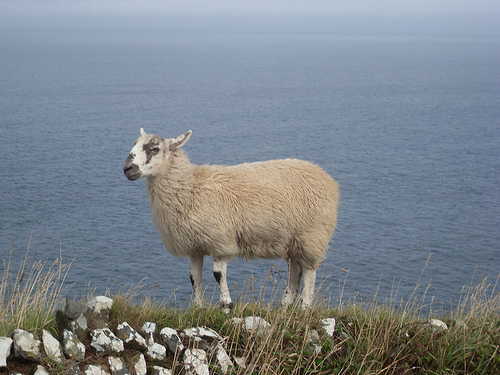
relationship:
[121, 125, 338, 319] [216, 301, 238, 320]
sheep has foot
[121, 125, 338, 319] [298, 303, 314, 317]
sheep has foot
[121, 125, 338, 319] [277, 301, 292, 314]
sheep has foot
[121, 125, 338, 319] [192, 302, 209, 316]
sheep has foot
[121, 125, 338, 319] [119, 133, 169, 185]
sheep has face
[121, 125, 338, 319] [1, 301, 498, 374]
sheep on hill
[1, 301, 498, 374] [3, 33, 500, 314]
hill next to water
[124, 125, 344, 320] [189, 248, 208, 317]
sheep has front leg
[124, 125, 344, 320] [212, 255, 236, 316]
sheep has front leg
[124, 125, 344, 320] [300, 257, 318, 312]
sheep has hind leg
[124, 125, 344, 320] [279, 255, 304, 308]
sheep has hind leg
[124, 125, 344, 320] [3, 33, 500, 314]
sheep above water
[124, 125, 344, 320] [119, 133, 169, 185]
sheep has face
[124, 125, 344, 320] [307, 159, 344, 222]
sheep has butt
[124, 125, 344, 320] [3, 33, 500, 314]
sheep beside water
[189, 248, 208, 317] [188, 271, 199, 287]
front leg has spot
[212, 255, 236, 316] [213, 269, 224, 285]
front leg has spot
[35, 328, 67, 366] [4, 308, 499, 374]
rock on ground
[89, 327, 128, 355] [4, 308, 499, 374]
rock on ground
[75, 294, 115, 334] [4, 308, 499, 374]
rock on ground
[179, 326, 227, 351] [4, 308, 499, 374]
rock on ground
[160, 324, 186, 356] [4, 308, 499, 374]
rock on ground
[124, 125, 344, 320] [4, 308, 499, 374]
sheep on ground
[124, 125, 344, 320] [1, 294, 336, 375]
sheep behind rocks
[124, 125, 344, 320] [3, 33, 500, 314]
sheep in front of water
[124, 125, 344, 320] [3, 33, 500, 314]
sheep before water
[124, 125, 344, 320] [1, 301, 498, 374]
sheep on hill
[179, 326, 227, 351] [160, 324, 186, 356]
rock next to rock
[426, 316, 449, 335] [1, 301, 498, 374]
rock on hill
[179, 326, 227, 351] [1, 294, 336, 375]
rock among rocks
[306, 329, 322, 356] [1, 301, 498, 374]
rock on hill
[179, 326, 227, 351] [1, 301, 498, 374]
rock on hill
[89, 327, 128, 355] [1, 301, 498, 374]
rock on hill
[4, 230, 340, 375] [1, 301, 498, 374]
grass on top of hill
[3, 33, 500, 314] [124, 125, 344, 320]
water behind sheep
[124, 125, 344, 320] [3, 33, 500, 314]
sheep overlooks water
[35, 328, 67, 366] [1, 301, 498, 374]
rock on hill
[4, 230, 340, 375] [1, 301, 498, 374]
grass on hill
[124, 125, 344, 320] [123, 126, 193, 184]
sheep has head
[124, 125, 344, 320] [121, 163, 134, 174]
sheep has nose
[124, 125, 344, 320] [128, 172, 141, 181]
sheep has mouth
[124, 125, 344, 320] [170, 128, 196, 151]
sheep has ear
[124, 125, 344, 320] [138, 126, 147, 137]
sheep has ear